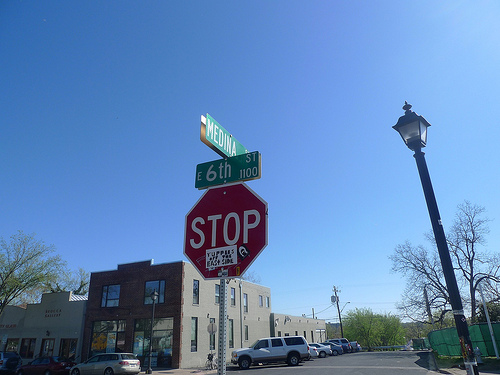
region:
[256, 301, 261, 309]
part of a house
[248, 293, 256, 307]
edge of a building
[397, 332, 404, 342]
part of a bush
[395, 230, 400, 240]
part of the sky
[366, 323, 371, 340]
edge of a road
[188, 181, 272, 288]
white and red sign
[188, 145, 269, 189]
green and white sign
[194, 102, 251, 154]
green and white sign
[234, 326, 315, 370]
white truck parked in the lot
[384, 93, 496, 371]
tall black light pole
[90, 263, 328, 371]
brick building in the background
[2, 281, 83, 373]
white store in the background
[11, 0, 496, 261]
clear sky in the color blue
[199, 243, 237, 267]
black and white sticker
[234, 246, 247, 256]
black and white sticker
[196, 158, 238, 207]
This road sign says 6th on it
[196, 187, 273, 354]
There is a Stop sign that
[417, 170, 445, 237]
There is a black lamp post that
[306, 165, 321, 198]
There is a dark blue sky visible here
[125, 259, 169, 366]
There is a red building that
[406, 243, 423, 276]
There is a dark brown tree here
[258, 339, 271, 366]
There is a white vehicle that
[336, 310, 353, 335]
There is a brown post that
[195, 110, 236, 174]
This says "Medina" on it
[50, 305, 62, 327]
There is a white building that is visible here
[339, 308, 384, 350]
a large green tree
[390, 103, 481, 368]
a tall black street lamp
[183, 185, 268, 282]
a red and white stop sign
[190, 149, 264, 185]
a green and white street sign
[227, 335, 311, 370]
a large white suv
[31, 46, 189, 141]
part of a blue sky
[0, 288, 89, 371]
a short white building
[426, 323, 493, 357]
part of a green fence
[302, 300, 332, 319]
an electrical power line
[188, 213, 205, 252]
White letter on sign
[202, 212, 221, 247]
White letter on sign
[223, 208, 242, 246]
White letter on sign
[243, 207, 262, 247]
White letter on sign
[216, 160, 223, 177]
White letter on sign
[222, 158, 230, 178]
White letter on sign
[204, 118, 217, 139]
White letter on sign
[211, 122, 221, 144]
White letter on sign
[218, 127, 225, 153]
White letter on sign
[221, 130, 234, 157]
White letter on sign